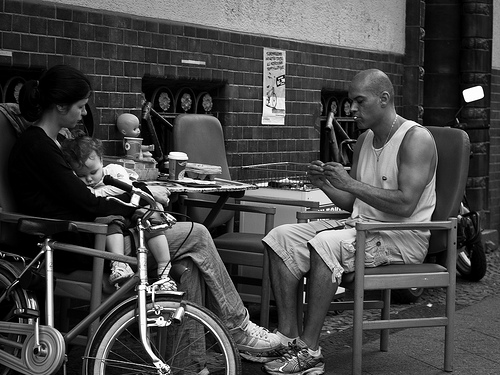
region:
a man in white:
[315, 55, 490, 355]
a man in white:
[354, 96, 434, 365]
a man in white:
[339, 22, 415, 329]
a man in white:
[388, 110, 498, 289]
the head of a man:
[346, 67, 401, 133]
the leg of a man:
[298, 215, 399, 340]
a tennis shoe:
[266, 333, 331, 373]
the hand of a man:
[317, 160, 356, 190]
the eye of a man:
[353, 91, 368, 106]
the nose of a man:
[348, 97, 361, 113]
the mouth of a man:
[348, 110, 366, 122]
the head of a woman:
[11, 62, 100, 134]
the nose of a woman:
[78, 102, 92, 117]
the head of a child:
[62, 125, 109, 192]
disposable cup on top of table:
[163, 150, 195, 190]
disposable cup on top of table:
[169, 151, 187, 184]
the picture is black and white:
[5, 3, 494, 307]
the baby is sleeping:
[44, 133, 199, 253]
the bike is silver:
[0, 182, 245, 365]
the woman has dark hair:
[3, 67, 104, 138]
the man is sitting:
[259, 62, 454, 341]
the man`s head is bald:
[297, 45, 409, 134]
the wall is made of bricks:
[190, 25, 314, 157]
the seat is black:
[2, 203, 75, 250]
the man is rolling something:
[274, 137, 361, 214]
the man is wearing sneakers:
[250, 315, 334, 374]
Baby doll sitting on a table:
[113, 109, 163, 165]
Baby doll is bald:
[116, 109, 142, 141]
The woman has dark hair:
[8, 54, 98, 133]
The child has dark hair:
[56, 130, 115, 196]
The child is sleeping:
[51, 135, 170, 241]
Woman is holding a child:
[11, 52, 208, 289]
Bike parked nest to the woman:
[1, 177, 239, 372]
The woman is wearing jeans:
[116, 210, 253, 341]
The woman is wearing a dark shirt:
[5, 117, 115, 247]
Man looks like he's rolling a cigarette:
[299, 67, 457, 231]